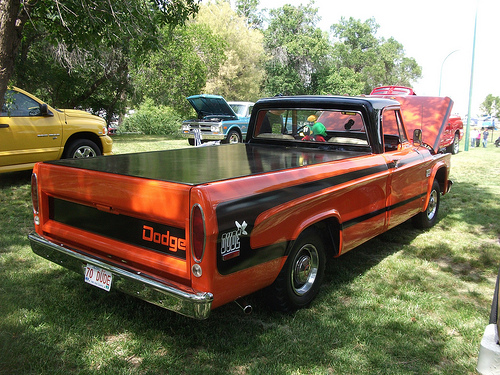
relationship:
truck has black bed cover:
[28, 94, 456, 327] [41, 140, 369, 187]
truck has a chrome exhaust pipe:
[28, 94, 456, 327] [234, 298, 257, 317]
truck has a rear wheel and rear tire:
[28, 94, 456, 327] [276, 231, 334, 309]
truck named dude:
[28, 94, 456, 327] [219, 229, 243, 262]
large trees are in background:
[1, 2, 422, 150] [2, 1, 500, 170]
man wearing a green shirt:
[301, 115, 329, 139] [305, 122, 329, 136]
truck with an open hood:
[28, 94, 456, 327] [310, 95, 456, 152]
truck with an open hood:
[180, 93, 302, 146] [186, 93, 240, 120]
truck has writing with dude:
[28, 94, 456, 327] [219, 229, 243, 262]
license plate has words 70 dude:
[84, 262, 114, 293] [86, 265, 112, 286]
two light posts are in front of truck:
[437, 6, 481, 159] [28, 94, 456, 327]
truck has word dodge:
[28, 94, 456, 327] [141, 223, 188, 253]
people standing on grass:
[470, 124, 491, 151] [3, 122, 499, 371]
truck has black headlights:
[180, 93, 302, 146] [209, 125, 221, 134]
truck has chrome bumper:
[28, 94, 456, 327] [28, 232, 215, 321]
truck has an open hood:
[28, 94, 456, 327] [310, 95, 456, 152]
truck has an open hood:
[180, 93, 302, 146] [186, 93, 240, 120]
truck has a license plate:
[28, 94, 456, 327] [84, 262, 114, 293]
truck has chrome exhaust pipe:
[28, 94, 456, 327] [234, 298, 257, 317]